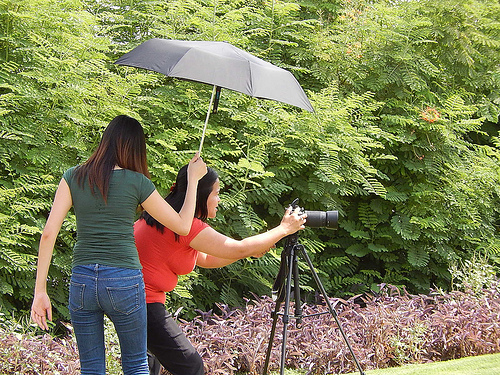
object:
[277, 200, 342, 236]
camera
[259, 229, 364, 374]
stand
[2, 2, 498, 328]
tree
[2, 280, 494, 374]
bush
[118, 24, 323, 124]
umberella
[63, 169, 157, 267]
green shirt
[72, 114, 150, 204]
hair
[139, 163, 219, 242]
hair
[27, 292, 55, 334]
hand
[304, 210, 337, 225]
lens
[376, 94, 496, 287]
tree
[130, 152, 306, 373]
woman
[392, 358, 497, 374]
grass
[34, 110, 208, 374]
ladies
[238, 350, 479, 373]
ground